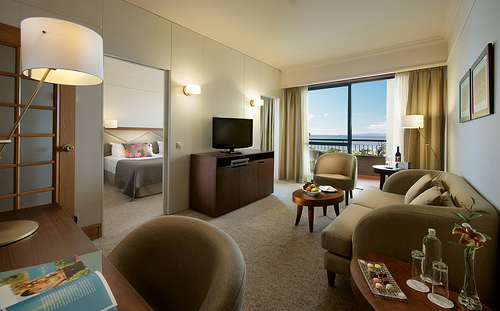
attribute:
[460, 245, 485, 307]
vase — clear, glass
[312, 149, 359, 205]
chair — brown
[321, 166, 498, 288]
couch — brown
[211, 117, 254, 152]
tv — off, black, flat screen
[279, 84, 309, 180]
curtains — tan, cream, seem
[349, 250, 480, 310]
table — wooden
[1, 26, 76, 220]
door — closed, opened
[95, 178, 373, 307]
floor — tan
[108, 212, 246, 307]
chair — tan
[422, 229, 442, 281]
bottle of water — clear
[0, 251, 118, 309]
magaine — open, opened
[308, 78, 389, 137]
sky — blue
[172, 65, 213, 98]
light — on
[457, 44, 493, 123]
pictures — framed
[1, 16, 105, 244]
table lamp — lit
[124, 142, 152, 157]
pillow — pink, brown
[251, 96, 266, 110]
wall light fixture — small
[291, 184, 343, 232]
coffee table — wooden